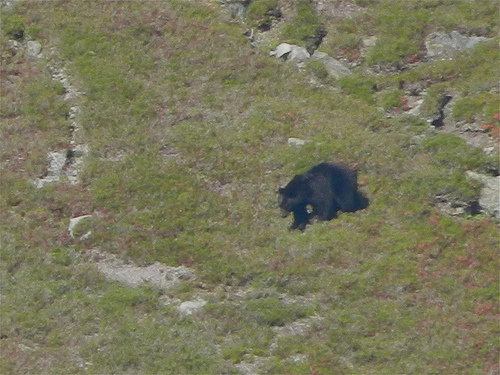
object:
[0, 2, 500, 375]
hill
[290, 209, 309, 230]
leg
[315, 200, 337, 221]
leg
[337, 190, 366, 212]
leg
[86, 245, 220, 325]
dirt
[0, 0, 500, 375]
ground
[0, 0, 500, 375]
field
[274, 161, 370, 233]
bear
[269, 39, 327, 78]
rock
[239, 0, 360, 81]
rocks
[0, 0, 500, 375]
grass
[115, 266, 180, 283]
gravel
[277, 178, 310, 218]
head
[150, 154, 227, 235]
ground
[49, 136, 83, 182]
gravel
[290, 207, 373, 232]
edge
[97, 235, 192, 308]
rock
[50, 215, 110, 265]
rock